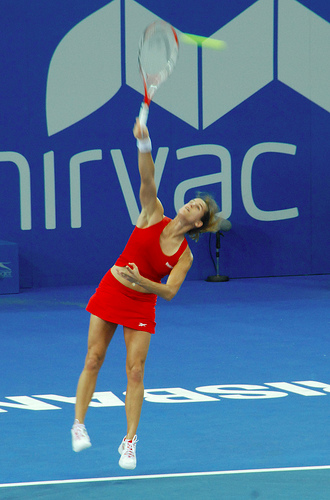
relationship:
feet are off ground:
[66, 424, 149, 470] [12, 460, 326, 500]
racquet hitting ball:
[135, 12, 183, 128] [177, 27, 234, 52]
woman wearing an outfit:
[61, 185, 232, 470] [74, 214, 186, 333]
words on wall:
[1, 134, 313, 239] [8, 5, 328, 283]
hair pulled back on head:
[204, 192, 226, 239] [179, 192, 219, 239]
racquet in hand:
[135, 12, 183, 128] [128, 118, 156, 150]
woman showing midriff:
[61, 185, 232, 470] [113, 273, 149, 292]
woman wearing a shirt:
[61, 185, 232, 470] [121, 219, 185, 289]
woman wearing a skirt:
[61, 185, 232, 470] [88, 275, 160, 334]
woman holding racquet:
[61, 185, 232, 470] [135, 12, 183, 128]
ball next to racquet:
[177, 27, 234, 52] [135, 12, 183, 128]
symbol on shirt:
[162, 259, 177, 270] [121, 219, 185, 289]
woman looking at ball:
[61, 185, 232, 470] [177, 27, 234, 52]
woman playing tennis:
[61, 185, 232, 470] [5, 5, 321, 499]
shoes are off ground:
[67, 417, 150, 474] [12, 460, 326, 500]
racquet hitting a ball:
[135, 12, 183, 128] [177, 27, 234, 52]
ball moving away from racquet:
[177, 27, 234, 52] [135, 12, 183, 128]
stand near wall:
[208, 228, 230, 287] [8, 5, 328, 283]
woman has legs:
[61, 185, 232, 470] [74, 310, 154, 436]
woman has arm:
[61, 185, 232, 470] [126, 120, 163, 211]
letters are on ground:
[9, 380, 328, 412] [12, 460, 326, 500]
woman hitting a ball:
[61, 185, 232, 470] [177, 27, 234, 52]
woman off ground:
[61, 185, 232, 470] [12, 460, 326, 500]